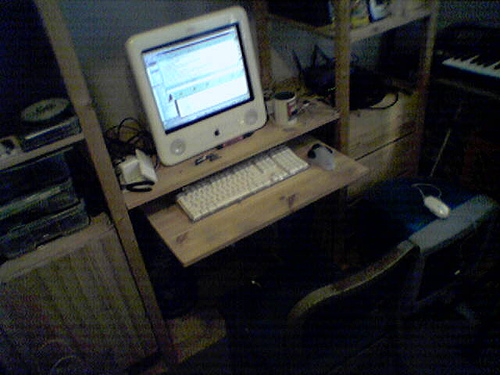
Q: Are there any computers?
A: Yes, there is a computer.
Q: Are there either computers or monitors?
A: Yes, there is a computer.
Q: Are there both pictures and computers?
A: No, there is a computer but no pictures.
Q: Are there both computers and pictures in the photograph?
A: No, there is a computer but no pictures.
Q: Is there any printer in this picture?
A: No, there are no printers.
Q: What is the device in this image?
A: The device is a computer.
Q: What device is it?
A: The device is a computer.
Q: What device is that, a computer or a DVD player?
A: That is a computer.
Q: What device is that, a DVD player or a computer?
A: That is a computer.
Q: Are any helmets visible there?
A: No, there are no helmets.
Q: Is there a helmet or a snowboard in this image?
A: No, there are no helmets or snowboards.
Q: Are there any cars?
A: No, there are no cars.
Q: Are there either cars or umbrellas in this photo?
A: No, there are no cars or umbrellas.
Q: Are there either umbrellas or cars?
A: No, there are no cars or umbrellas.